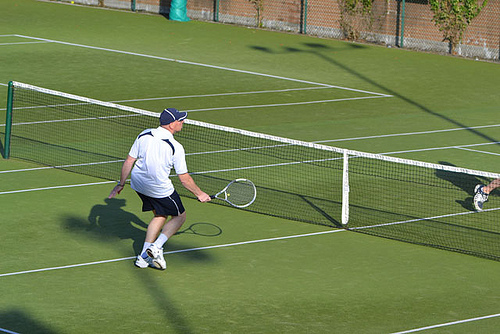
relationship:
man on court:
[102, 102, 264, 282] [0, 0, 498, 333]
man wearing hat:
[102, 102, 264, 282] [157, 108, 190, 126]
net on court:
[4, 72, 500, 255] [0, 0, 498, 333]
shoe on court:
[472, 176, 488, 213] [0, 0, 498, 333]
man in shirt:
[102, 102, 264, 282] [126, 124, 187, 205]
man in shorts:
[102, 102, 264, 282] [131, 189, 194, 222]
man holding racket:
[102, 102, 264, 282] [199, 173, 261, 220]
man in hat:
[102, 102, 264, 282] [157, 108, 190, 126]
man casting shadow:
[102, 102, 264, 282] [77, 191, 224, 247]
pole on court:
[235, 35, 499, 159] [0, 0, 498, 333]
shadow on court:
[77, 191, 224, 247] [0, 0, 498, 333]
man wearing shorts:
[102, 102, 264, 282] [131, 189, 194, 222]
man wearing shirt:
[102, 102, 264, 282] [126, 124, 187, 205]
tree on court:
[428, 2, 479, 57] [0, 0, 498, 333]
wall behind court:
[156, 0, 499, 61] [0, 0, 498, 333]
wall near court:
[156, 0, 499, 61] [0, 0, 498, 333]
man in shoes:
[102, 102, 264, 282] [134, 240, 175, 281]